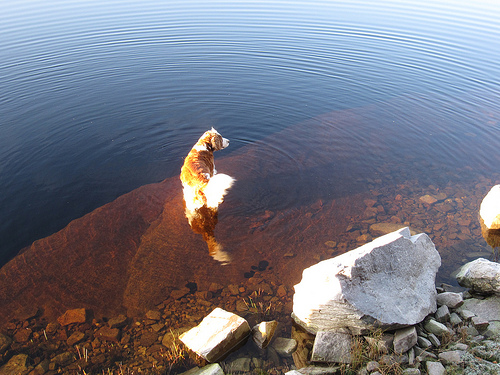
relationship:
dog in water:
[179, 126, 238, 265] [80, 24, 472, 188]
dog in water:
[179, 126, 238, 265] [0, 2, 499, 329]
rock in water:
[178, 307, 252, 363] [253, 32, 354, 97]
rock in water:
[478, 180, 499, 239] [2, 2, 497, 373]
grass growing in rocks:
[66, 303, 291, 373] [35, 180, 498, 368]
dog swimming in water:
[171, 130, 246, 265] [2, 2, 497, 373]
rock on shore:
[291, 226, 442, 335] [18, 185, 497, 366]